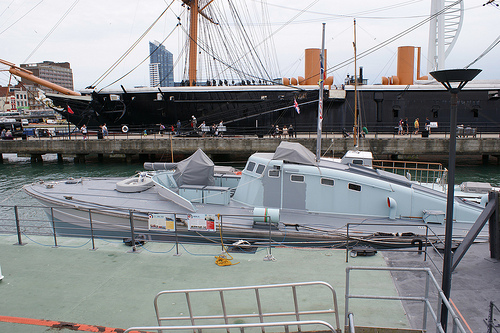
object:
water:
[1, 155, 500, 235]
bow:
[30, 85, 93, 120]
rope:
[215, 215, 239, 268]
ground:
[0, 234, 497, 329]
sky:
[0, 1, 500, 89]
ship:
[44, 0, 498, 134]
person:
[80, 124, 88, 139]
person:
[102, 123, 109, 139]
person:
[288, 125, 294, 138]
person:
[398, 118, 403, 136]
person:
[425, 117, 431, 135]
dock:
[0, 136, 498, 162]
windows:
[349, 183, 361, 191]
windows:
[321, 178, 334, 186]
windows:
[291, 175, 303, 182]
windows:
[268, 170, 279, 177]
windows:
[246, 161, 265, 174]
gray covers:
[174, 148, 216, 187]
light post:
[428, 69, 482, 333]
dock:
[0, 235, 497, 332]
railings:
[154, 281, 338, 331]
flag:
[294, 96, 301, 113]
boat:
[20, 141, 497, 251]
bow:
[22, 177, 108, 210]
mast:
[178, 1, 276, 84]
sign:
[149, 213, 177, 232]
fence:
[0, 204, 271, 256]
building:
[19, 60, 73, 97]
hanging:
[122, 125, 129, 132]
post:
[438, 90, 457, 331]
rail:
[342, 267, 466, 333]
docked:
[0, 150, 499, 333]